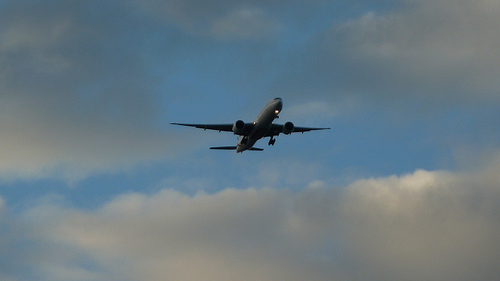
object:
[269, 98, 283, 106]
tip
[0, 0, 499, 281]
sky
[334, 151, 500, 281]
cloud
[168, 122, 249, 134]
wing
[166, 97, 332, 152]
plane